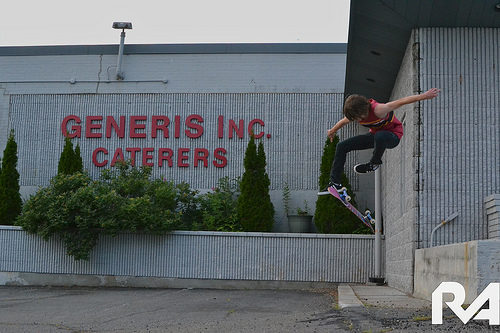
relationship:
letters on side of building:
[63, 110, 266, 171] [1, 37, 494, 285]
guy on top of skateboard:
[325, 91, 435, 181] [326, 187, 376, 229]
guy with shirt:
[325, 91, 435, 181] [361, 103, 405, 138]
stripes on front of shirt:
[358, 111, 395, 127] [361, 103, 405, 138]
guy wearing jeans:
[325, 91, 435, 181] [329, 132, 398, 181]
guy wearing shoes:
[325, 91, 435, 181] [311, 161, 379, 198]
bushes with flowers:
[26, 170, 189, 251] [45, 186, 151, 206]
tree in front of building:
[319, 133, 356, 233] [1, 37, 494, 285]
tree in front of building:
[238, 137, 275, 230] [1, 37, 494, 285]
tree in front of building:
[58, 139, 85, 174] [1, 37, 494, 285]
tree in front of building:
[3, 131, 25, 220] [1, 37, 494, 285]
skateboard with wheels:
[326, 187, 376, 229] [339, 188, 381, 221]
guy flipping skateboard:
[325, 91, 435, 181] [326, 187, 376, 229]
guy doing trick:
[325, 91, 435, 181] [320, 76, 432, 229]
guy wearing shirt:
[325, 91, 435, 181] [361, 103, 405, 138]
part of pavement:
[350, 307, 485, 331] [5, 278, 355, 332]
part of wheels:
[340, 191, 348, 199] [339, 188, 381, 221]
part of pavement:
[329, 186, 343, 199] [5, 278, 355, 332]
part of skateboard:
[329, 186, 343, 199] [326, 187, 376, 229]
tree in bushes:
[238, 137, 275, 230] [26, 170, 189, 261]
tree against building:
[238, 137, 275, 230] [1, 37, 494, 285]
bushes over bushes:
[26, 170, 189, 251] [26, 170, 189, 261]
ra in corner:
[431, 282, 498, 325] [416, 261, 499, 332]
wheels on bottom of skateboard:
[339, 188, 381, 221] [326, 187, 376, 229]